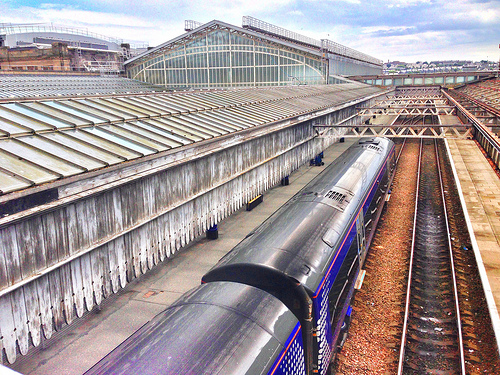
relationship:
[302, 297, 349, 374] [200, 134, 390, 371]
pattern on side of train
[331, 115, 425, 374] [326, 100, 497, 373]
gravel near train tracks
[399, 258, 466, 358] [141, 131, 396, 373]
tracks next train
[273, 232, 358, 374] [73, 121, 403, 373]
pink stripe on train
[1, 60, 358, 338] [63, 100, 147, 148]
building has metal roof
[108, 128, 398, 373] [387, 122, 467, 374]
train next tracks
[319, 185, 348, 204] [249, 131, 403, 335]
vent on top of train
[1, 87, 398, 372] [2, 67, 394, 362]
fence on side of building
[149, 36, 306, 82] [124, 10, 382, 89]
window on building